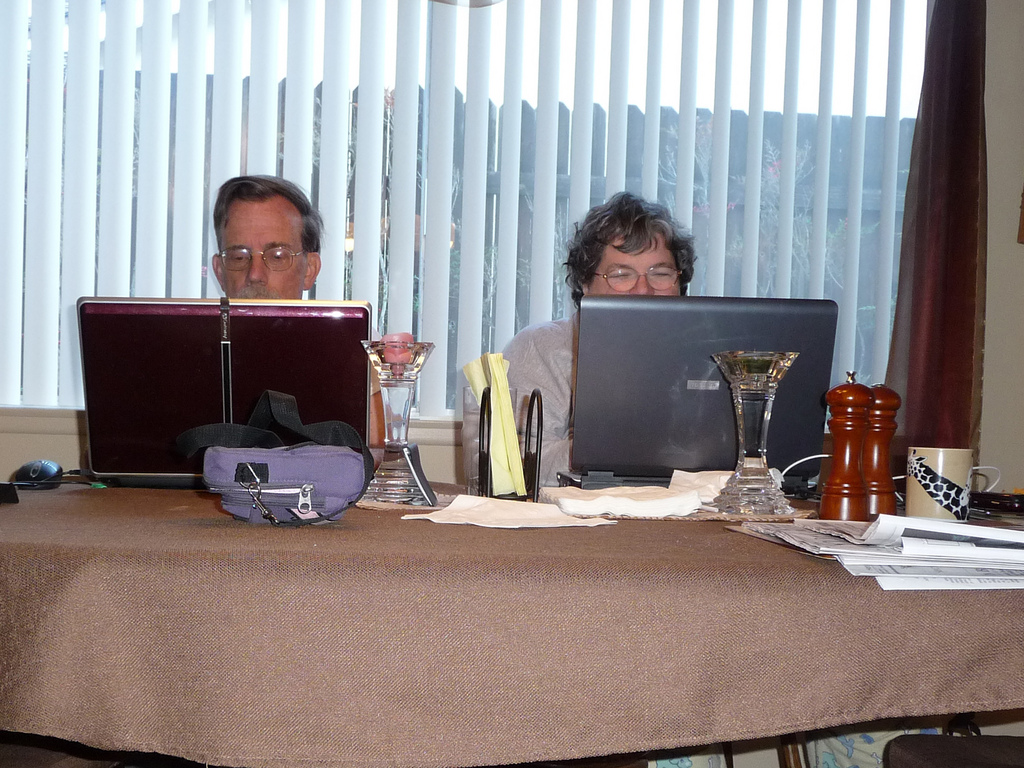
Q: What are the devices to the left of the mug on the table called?
A: The devices are computers.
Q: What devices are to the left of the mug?
A: The devices are computers.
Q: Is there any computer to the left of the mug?
A: Yes, there are computers to the left of the mug.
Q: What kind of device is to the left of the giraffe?
A: The devices are computers.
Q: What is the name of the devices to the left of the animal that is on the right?
A: The devices are computers.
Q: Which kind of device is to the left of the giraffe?
A: The devices are computers.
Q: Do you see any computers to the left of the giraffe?
A: Yes, there are computers to the left of the giraffe.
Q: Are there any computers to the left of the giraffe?
A: Yes, there are computers to the left of the giraffe.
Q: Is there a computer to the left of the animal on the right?
A: Yes, there are computers to the left of the giraffe.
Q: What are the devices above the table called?
A: The devices are computers.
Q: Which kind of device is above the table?
A: The devices are computers.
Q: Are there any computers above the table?
A: Yes, there are computers above the table.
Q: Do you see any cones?
A: No, there are no cones.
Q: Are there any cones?
A: No, there are no cones.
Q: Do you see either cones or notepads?
A: No, there are no cones or notepads.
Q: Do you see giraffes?
A: Yes, there is a giraffe.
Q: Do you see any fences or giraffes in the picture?
A: Yes, there is a giraffe.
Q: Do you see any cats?
A: No, there are no cats.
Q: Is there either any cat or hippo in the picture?
A: No, there are no cats or hippos.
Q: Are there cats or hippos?
A: No, there are no cats or hippos.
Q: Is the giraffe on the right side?
A: Yes, the giraffe is on the right of the image.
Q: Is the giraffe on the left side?
A: No, the giraffe is on the right of the image.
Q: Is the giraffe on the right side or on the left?
A: The giraffe is on the right of the image.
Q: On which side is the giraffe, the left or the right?
A: The giraffe is on the right of the image.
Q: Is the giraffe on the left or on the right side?
A: The giraffe is on the right of the image.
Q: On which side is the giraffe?
A: The giraffe is on the right of the image.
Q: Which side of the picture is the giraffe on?
A: The giraffe is on the right of the image.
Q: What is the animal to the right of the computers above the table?
A: The animal is a giraffe.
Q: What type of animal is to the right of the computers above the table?
A: The animal is a giraffe.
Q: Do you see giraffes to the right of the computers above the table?
A: Yes, there is a giraffe to the right of the computers.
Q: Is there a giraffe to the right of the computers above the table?
A: Yes, there is a giraffe to the right of the computers.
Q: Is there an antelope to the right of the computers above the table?
A: No, there is a giraffe to the right of the computers.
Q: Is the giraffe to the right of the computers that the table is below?
A: Yes, the giraffe is to the right of the computers.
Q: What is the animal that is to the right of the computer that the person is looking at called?
A: The animal is a giraffe.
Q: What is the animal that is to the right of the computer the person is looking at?
A: The animal is a giraffe.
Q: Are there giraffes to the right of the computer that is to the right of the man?
A: Yes, there is a giraffe to the right of the computer.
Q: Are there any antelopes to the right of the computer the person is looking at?
A: No, there is a giraffe to the right of the computer.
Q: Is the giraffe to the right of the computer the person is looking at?
A: Yes, the giraffe is to the right of the computer.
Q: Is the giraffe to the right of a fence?
A: No, the giraffe is to the right of the computer.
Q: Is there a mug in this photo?
A: Yes, there is a mug.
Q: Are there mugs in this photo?
A: Yes, there is a mug.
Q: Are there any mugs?
A: Yes, there is a mug.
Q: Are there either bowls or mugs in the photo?
A: Yes, there is a mug.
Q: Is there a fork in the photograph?
A: No, there are no forks.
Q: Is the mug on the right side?
A: Yes, the mug is on the right of the image.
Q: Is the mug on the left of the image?
A: No, the mug is on the right of the image.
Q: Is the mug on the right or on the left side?
A: The mug is on the right of the image.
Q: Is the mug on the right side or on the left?
A: The mug is on the right of the image.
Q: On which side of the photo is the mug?
A: The mug is on the right of the image.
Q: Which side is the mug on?
A: The mug is on the right of the image.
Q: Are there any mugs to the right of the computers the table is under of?
A: Yes, there is a mug to the right of the computers.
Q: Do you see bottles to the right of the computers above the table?
A: No, there is a mug to the right of the computers.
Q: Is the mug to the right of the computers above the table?
A: Yes, the mug is to the right of the computers.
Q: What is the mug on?
A: The mug is on the table.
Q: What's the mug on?
A: The mug is on the table.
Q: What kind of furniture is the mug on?
A: The mug is on the table.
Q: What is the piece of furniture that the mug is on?
A: The piece of furniture is a table.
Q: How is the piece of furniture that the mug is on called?
A: The piece of furniture is a table.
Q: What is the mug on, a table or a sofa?
A: The mug is on a table.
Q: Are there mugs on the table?
A: Yes, there is a mug on the table.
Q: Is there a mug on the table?
A: Yes, there is a mug on the table.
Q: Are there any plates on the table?
A: No, there is a mug on the table.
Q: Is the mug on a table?
A: Yes, the mug is on a table.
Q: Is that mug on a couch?
A: No, the mug is on a table.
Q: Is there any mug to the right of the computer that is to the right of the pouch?
A: Yes, there is a mug to the right of the computer.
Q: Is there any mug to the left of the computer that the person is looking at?
A: No, the mug is to the right of the computer.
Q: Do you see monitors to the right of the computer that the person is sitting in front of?
A: No, there is a mug to the right of the computer.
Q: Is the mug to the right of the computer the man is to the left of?
A: Yes, the mug is to the right of the computer.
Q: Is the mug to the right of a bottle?
A: No, the mug is to the right of the computer.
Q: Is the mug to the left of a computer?
A: No, the mug is to the right of a computer.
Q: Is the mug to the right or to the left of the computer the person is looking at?
A: The mug is to the right of the computer.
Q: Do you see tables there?
A: Yes, there is a table.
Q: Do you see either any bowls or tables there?
A: Yes, there is a table.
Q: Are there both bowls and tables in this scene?
A: No, there is a table but no bowls.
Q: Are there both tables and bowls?
A: No, there is a table but no bowls.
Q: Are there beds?
A: No, there are no beds.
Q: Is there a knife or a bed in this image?
A: No, there are no beds or knives.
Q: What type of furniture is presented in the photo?
A: The furniture is a table.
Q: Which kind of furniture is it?
A: The piece of furniture is a table.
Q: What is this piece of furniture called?
A: This is a table.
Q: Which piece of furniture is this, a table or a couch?
A: This is a table.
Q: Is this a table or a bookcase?
A: This is a table.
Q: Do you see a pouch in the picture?
A: Yes, there is a pouch.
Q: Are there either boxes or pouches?
A: Yes, there is a pouch.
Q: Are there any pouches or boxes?
A: Yes, there is a pouch.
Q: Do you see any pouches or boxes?
A: Yes, there is a pouch.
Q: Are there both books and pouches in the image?
A: No, there is a pouch but no books.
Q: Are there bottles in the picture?
A: No, there are no bottles.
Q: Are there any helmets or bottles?
A: No, there are no bottles or helmets.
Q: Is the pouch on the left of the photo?
A: Yes, the pouch is on the left of the image.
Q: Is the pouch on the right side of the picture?
A: No, the pouch is on the left of the image.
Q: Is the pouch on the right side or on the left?
A: The pouch is on the left of the image.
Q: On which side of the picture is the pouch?
A: The pouch is on the left of the image.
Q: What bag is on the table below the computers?
A: The bag is a pouch.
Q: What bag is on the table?
A: The bag is a pouch.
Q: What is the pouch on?
A: The pouch is on the table.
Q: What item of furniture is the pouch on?
A: The pouch is on the table.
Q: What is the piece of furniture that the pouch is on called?
A: The piece of furniture is a table.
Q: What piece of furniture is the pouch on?
A: The pouch is on the table.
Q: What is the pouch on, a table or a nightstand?
A: The pouch is on a table.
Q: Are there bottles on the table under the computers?
A: No, there is a pouch on the table.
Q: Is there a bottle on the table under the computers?
A: No, there is a pouch on the table.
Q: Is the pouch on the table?
A: Yes, the pouch is on the table.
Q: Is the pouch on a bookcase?
A: No, the pouch is on the table.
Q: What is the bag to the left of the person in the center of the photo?
A: The bag is a pouch.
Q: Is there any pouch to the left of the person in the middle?
A: Yes, there is a pouch to the left of the person.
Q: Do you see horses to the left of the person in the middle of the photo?
A: No, there is a pouch to the left of the person.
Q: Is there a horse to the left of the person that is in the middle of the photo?
A: No, there is a pouch to the left of the person.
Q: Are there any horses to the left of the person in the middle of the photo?
A: No, there is a pouch to the left of the person.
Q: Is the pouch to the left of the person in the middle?
A: Yes, the pouch is to the left of the person.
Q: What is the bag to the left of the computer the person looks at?
A: The bag is a pouch.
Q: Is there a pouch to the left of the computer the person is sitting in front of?
A: Yes, there is a pouch to the left of the computer.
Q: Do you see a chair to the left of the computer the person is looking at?
A: No, there is a pouch to the left of the computer.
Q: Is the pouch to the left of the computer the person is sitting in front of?
A: Yes, the pouch is to the left of the computer.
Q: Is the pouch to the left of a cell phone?
A: No, the pouch is to the left of the computer.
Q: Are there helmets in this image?
A: No, there are no helmets.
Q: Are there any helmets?
A: No, there are no helmets.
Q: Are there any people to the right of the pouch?
A: Yes, there is a person to the right of the pouch.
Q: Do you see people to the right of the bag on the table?
A: Yes, there is a person to the right of the pouch.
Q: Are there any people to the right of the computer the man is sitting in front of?
A: Yes, there is a person to the right of the computer.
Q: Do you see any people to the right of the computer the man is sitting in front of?
A: Yes, there is a person to the right of the computer.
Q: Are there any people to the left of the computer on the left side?
A: No, the person is to the right of the computer.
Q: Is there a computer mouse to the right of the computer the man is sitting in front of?
A: No, there is a person to the right of the computer.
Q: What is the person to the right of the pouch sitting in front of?
A: The person is sitting in front of the computer.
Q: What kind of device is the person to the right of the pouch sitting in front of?
A: The person is sitting in front of the computer.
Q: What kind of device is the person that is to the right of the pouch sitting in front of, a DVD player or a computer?
A: The person is sitting in front of a computer.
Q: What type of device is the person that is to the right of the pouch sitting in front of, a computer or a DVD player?
A: The person is sitting in front of a computer.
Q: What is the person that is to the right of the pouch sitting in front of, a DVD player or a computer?
A: The person is sitting in front of a computer.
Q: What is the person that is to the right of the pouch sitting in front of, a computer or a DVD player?
A: The person is sitting in front of a computer.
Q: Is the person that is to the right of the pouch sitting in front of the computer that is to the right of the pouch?
A: Yes, the person is sitting in front of the computer.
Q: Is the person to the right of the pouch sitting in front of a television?
A: No, the person is sitting in front of the computer.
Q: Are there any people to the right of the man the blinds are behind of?
A: Yes, there is a person to the right of the man.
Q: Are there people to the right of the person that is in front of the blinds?
A: Yes, there is a person to the right of the man.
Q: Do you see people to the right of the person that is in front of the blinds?
A: Yes, there is a person to the right of the man.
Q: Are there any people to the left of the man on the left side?
A: No, the person is to the right of the man.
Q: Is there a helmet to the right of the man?
A: No, there is a person to the right of the man.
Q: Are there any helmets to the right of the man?
A: No, there is a person to the right of the man.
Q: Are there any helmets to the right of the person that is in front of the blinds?
A: No, there is a person to the right of the man.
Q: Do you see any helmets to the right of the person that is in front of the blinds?
A: No, there is a person to the right of the man.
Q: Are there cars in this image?
A: No, there are no cars.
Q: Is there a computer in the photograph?
A: Yes, there is a computer.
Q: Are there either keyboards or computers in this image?
A: Yes, there is a computer.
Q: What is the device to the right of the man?
A: The device is a computer.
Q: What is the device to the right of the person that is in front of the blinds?
A: The device is a computer.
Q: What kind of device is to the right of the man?
A: The device is a computer.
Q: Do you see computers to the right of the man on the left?
A: Yes, there is a computer to the right of the man.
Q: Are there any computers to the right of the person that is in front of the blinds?
A: Yes, there is a computer to the right of the man.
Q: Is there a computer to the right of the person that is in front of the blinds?
A: Yes, there is a computer to the right of the man.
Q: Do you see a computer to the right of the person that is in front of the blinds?
A: Yes, there is a computer to the right of the man.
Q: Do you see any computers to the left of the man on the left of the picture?
A: No, the computer is to the right of the man.